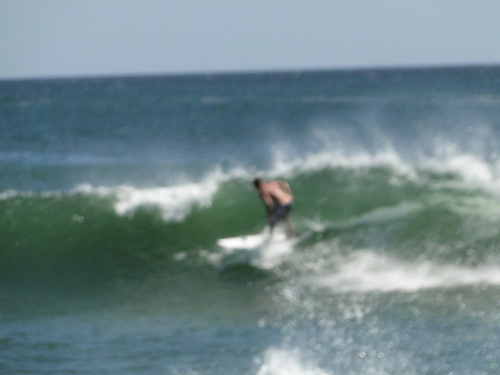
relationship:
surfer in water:
[246, 168, 299, 242] [1, 77, 499, 374]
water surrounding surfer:
[1, 77, 499, 374] [246, 168, 299, 242]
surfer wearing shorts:
[246, 168, 299, 242] [265, 200, 306, 226]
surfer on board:
[246, 168, 299, 242] [210, 226, 301, 256]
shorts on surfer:
[265, 200, 306, 226] [246, 168, 299, 242]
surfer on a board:
[246, 168, 299, 242] [210, 226, 301, 256]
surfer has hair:
[246, 168, 299, 242] [248, 177, 265, 186]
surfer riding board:
[246, 168, 299, 242] [210, 226, 301, 256]